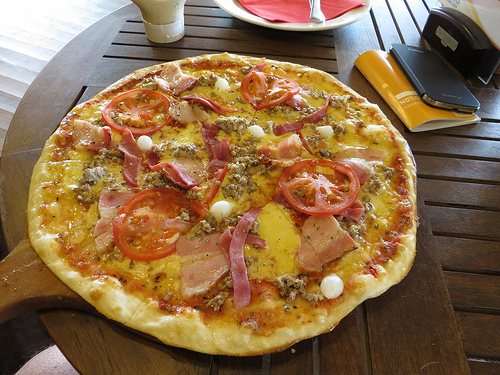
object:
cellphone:
[389, 39, 481, 112]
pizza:
[27, 53, 417, 356]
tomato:
[278, 159, 361, 214]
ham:
[229, 207, 262, 308]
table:
[0, 0, 499, 374]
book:
[354, 49, 482, 132]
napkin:
[238, 0, 366, 23]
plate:
[212, 0, 372, 31]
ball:
[320, 273, 344, 299]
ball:
[137, 135, 152, 151]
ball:
[211, 201, 232, 219]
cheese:
[244, 202, 302, 282]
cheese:
[110, 257, 178, 296]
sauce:
[373, 153, 411, 264]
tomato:
[112, 188, 208, 262]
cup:
[128, 0, 187, 44]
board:
[0, 235, 99, 320]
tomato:
[101, 88, 172, 136]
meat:
[294, 213, 358, 273]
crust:
[184, 328, 284, 356]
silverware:
[307, 0, 327, 23]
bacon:
[273, 92, 333, 136]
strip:
[118, 127, 143, 186]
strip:
[146, 146, 199, 189]